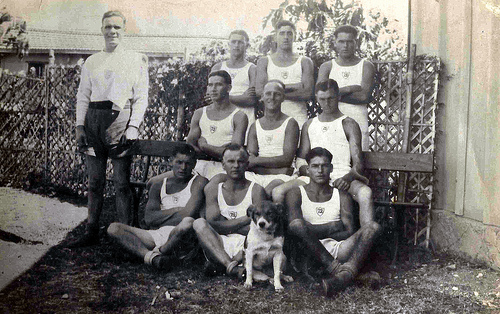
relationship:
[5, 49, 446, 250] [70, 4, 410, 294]
fence behind men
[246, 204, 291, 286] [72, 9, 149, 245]
dog by coach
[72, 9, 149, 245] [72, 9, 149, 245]
coach standing apart from other coach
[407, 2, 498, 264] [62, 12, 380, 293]
wall by men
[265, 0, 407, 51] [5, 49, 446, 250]
tree grows behind fence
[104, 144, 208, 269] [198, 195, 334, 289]
man posing together with dog